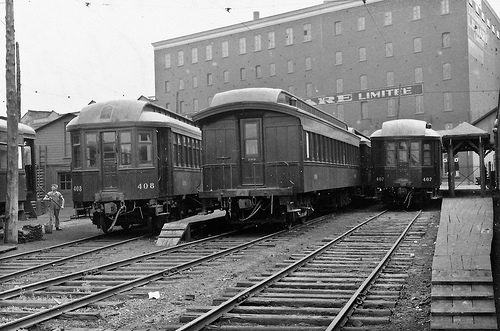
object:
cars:
[193, 87, 372, 229]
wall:
[155, 0, 472, 142]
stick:
[36, 165, 48, 217]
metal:
[350, 226, 406, 309]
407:
[422, 176, 432, 182]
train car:
[361, 115, 446, 202]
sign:
[295, 84, 426, 105]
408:
[137, 182, 155, 189]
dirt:
[111, 244, 257, 306]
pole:
[3, 0, 20, 243]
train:
[63, 93, 206, 239]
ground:
[215, 147, 382, 260]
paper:
[146, 290, 161, 300]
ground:
[1, 200, 439, 328]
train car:
[64, 96, 193, 208]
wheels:
[99, 210, 115, 235]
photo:
[1, 0, 498, 331]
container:
[190, 86, 371, 230]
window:
[356, 15, 363, 30]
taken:
[1, 0, 500, 331]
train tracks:
[1, 209, 431, 329]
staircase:
[432, 195, 499, 329]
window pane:
[298, 25, 311, 42]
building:
[146, 0, 499, 155]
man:
[42, 182, 66, 231]